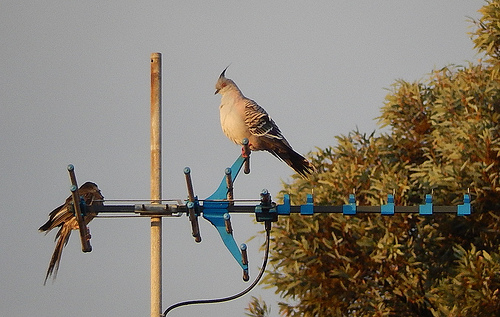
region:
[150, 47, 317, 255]
bird on a pole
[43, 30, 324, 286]
two birds on a pole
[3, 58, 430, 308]
two birds on a metal pole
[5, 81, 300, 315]
birds on a metal pole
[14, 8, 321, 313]
a pole with birds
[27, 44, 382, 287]
a pole with two birds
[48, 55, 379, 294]
a metal pole with birds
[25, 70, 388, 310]
a metal pole with two birds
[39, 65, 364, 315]
birds sitting down outside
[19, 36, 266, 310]
two birds standing outside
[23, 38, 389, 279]
two birds are on an aerial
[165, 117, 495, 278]
the aeial is blue in colour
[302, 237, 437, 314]
the tree is green in colour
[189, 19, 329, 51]
the sky is dark in colour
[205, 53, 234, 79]
the bird has a hair on the head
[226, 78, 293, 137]
the wing is white and black in colour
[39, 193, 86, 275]
the tail is long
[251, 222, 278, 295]
the aerial has a black cable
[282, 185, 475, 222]
the aerial has blue metals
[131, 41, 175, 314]
the pole is brown in colour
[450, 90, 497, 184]
Brown and green leaves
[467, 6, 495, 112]
Brown and green leaves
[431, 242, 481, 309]
Brown and green leaves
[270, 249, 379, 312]
Brown and green leaves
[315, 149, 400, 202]
Brown and green leaves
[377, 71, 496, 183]
Brown and green leaves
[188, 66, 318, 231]
A big brown bird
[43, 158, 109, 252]
A big brown bird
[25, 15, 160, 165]
A grey sky background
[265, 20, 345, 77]
A grey sky background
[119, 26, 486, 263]
A blue and black tv erial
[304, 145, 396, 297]
brown and green leaves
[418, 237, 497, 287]
brown and green leaves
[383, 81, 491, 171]
brown and green leaves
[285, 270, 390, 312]
brown and green leaves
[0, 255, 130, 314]
A grey sky background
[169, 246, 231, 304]
A grey sky background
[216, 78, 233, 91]
Bird has red eye.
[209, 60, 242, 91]
Black spikey feather on bird's head.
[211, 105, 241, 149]
Bird has white chest.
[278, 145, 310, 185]
Bird has black tail feathers.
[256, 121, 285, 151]
Bird has black,white, and gray wing.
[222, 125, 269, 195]
Bird is perched on pole.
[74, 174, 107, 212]
Bird has head tucked into chest.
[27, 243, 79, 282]
Bird has black tail feathers.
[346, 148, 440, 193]
Green leaves on tree.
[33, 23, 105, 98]
Sky is blue and clear.